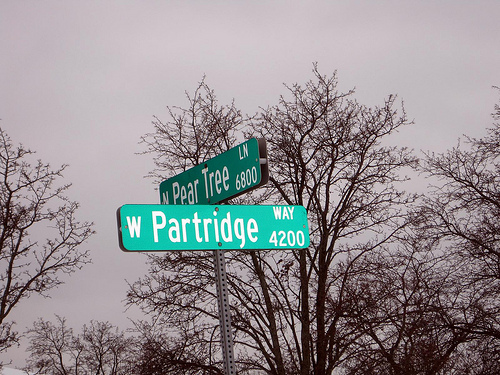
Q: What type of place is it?
A: It is a field.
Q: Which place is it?
A: It is a field.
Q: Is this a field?
A: Yes, it is a field.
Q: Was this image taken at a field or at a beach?
A: It was taken at a field.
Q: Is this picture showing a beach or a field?
A: It is showing a field.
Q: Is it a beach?
A: No, it is a field.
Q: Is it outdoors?
A: Yes, it is outdoors.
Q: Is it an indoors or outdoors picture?
A: It is outdoors.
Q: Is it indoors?
A: No, it is outdoors.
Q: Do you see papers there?
A: No, there are no papers.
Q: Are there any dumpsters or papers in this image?
A: No, there are no papers or dumpsters.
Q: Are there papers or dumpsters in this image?
A: No, there are no papers or dumpsters.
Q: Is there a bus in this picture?
A: No, there are no buses.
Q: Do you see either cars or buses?
A: No, there are no buses or cars.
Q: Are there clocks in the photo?
A: No, there are no clocks.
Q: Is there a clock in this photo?
A: No, there are no clocks.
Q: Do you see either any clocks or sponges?
A: No, there are no clocks or sponges.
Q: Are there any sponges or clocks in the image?
A: No, there are no clocks or sponges.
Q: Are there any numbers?
A: Yes, there are numbers.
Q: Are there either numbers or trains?
A: Yes, there are numbers.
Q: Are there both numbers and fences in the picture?
A: No, there are numbers but no fences.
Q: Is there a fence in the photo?
A: No, there are no fences.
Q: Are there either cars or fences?
A: No, there are no fences or cars.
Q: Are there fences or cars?
A: No, there are no fences or cars.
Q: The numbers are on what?
A: The numbers are on the sign.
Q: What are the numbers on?
A: The numbers are on the sign.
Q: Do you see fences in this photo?
A: No, there are no fences.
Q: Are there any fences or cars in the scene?
A: No, there are no fences or cars.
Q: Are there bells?
A: No, there are no bells.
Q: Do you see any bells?
A: No, there are no bells.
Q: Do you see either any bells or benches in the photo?
A: No, there are no bells or benches.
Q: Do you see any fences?
A: No, there are no fences.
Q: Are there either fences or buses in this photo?
A: No, there are no fences or buses.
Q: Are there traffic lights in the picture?
A: No, there are no traffic lights.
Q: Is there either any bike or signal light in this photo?
A: No, there are no traffic lights or bikes.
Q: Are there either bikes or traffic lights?
A: No, there are no traffic lights or bikes.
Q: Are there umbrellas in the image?
A: No, there are no umbrellas.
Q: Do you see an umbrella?
A: No, there are no umbrellas.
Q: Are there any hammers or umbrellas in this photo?
A: No, there are no umbrellas or hammers.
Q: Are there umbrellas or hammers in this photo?
A: No, there are no umbrellas or hammers.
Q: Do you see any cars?
A: No, there are no cars.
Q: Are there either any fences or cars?
A: No, there are no cars or fences.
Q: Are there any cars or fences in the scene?
A: No, there are no cars or fences.